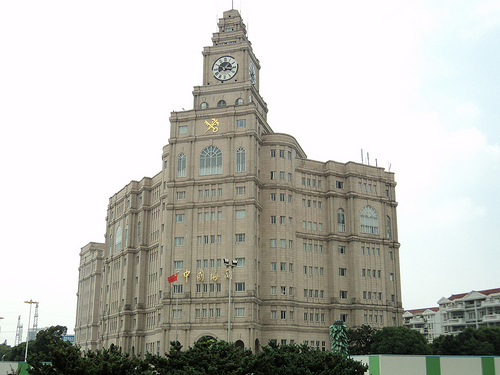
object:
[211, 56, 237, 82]
clock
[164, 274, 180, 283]
flag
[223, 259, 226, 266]
street light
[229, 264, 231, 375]
pole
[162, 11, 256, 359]
front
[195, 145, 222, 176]
windows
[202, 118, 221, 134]
logo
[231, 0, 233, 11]
antenna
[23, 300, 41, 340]
crane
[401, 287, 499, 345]
apartment building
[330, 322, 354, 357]
tree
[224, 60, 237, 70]
time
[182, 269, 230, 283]
emblems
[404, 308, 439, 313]
roof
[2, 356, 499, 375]
wall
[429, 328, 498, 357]
trees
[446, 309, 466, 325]
balconies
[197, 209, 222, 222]
windows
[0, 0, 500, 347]
sky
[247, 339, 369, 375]
bushes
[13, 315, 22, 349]
tower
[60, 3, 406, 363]
building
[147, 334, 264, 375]
trees